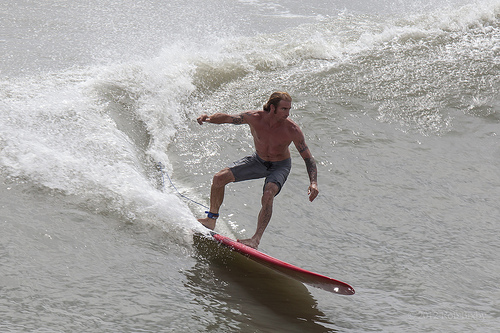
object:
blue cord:
[155, 162, 209, 209]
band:
[205, 211, 220, 219]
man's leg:
[255, 171, 286, 238]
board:
[210, 230, 355, 295]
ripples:
[9, 194, 216, 326]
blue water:
[0, 0, 499, 332]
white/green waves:
[3, 40, 216, 224]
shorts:
[225, 152, 291, 197]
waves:
[0, 0, 497, 331]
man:
[195, 91, 319, 249]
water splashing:
[2, 108, 199, 242]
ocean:
[2, 0, 500, 333]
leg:
[210, 160, 259, 220]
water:
[0, 0, 499, 332]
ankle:
[204, 208, 218, 222]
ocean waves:
[11, 0, 499, 219]